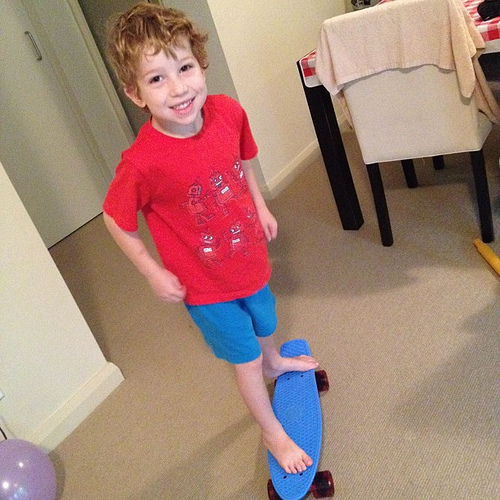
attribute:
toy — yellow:
[467, 241, 500, 283]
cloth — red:
[287, 2, 499, 84]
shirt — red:
[93, 128, 301, 297]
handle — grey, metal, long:
[23, 27, 50, 73]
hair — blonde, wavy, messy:
[98, 0, 212, 81]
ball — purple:
[1, 436, 61, 496]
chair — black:
[326, 6, 500, 240]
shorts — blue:
[179, 284, 299, 357]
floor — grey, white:
[21, 100, 472, 499]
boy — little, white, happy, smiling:
[96, 8, 311, 473]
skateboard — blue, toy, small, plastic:
[268, 338, 320, 499]